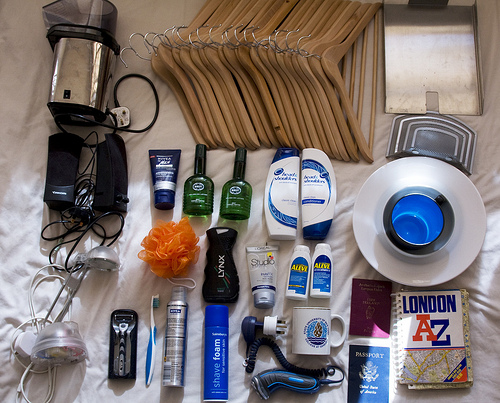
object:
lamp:
[8, 246, 121, 403]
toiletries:
[148, 149, 182, 211]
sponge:
[137, 216, 201, 289]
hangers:
[250, 0, 322, 151]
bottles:
[264, 148, 301, 241]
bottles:
[300, 148, 338, 240]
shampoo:
[202, 226, 241, 304]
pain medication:
[309, 243, 333, 299]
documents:
[347, 278, 392, 339]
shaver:
[249, 367, 325, 401]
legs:
[240, 314, 345, 400]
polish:
[182, 143, 215, 216]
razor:
[106, 307, 139, 378]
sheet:
[0, 0, 500, 403]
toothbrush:
[143, 293, 161, 386]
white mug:
[290, 304, 347, 360]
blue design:
[303, 317, 330, 349]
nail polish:
[219, 148, 253, 221]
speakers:
[39, 132, 138, 272]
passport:
[346, 345, 392, 403]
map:
[389, 287, 475, 391]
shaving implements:
[240, 310, 345, 401]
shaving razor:
[105, 307, 140, 384]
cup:
[389, 192, 444, 246]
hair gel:
[245, 240, 281, 309]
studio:
[250, 252, 275, 267]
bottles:
[390, 288, 474, 389]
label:
[301, 159, 331, 223]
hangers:
[232, 0, 313, 150]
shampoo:
[263, 147, 301, 240]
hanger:
[271, 0, 358, 163]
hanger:
[283, 0, 369, 164]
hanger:
[250, 0, 333, 160]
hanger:
[296, 0, 378, 164]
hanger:
[250, 0, 347, 160]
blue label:
[288, 256, 309, 295]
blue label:
[313, 255, 332, 294]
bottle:
[285, 245, 311, 301]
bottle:
[309, 241, 334, 299]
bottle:
[201, 226, 240, 304]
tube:
[245, 240, 280, 308]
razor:
[36, 0, 159, 147]